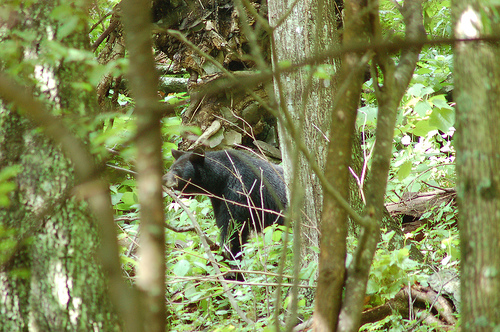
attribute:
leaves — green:
[113, 190, 130, 207]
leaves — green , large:
[423, 96, 455, 133]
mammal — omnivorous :
[158, 142, 294, 261]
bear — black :
[153, 138, 323, 245]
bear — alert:
[160, 142, 309, 272]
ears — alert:
[172, 145, 206, 165]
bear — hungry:
[165, 145, 287, 278]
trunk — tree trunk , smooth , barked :
[266, 0, 403, 268]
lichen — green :
[267, 0, 341, 265]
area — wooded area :
[36, 59, 164, 281]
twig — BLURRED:
[161, 58, 291, 108]